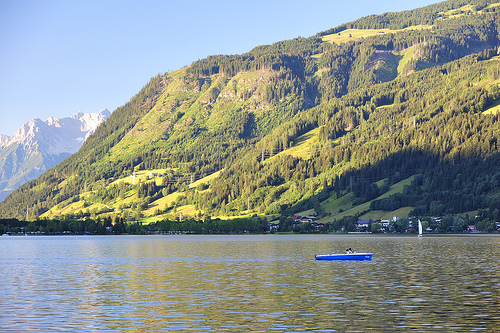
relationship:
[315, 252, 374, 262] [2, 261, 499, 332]
boat on top of water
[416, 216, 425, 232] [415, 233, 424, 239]
sail on top of boat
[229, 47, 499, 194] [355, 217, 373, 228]
green hill behind house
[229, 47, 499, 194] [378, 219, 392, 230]
green hill behind house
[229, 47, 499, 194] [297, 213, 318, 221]
green hill behind house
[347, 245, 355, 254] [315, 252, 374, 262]
person on top of boat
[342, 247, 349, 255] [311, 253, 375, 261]
person on top of boat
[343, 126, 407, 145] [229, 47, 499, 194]
wires on side of hill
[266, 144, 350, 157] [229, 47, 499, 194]
wires on side of hill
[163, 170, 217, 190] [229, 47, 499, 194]
wires on side of hill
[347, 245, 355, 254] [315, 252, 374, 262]
person inside of boat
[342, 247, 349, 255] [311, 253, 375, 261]
person inside of canoe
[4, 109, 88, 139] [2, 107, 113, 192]
snow on top of mountain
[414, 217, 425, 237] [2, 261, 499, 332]
sailboat on top of water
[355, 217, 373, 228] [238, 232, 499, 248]
house on top of water edge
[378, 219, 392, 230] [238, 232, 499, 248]
house on top of water edge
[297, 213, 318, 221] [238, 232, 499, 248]
house on top of water edge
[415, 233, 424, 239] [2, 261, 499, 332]
boat on top of water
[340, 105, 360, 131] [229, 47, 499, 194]
tree on side of mountain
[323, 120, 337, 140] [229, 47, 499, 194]
tree on side of mountain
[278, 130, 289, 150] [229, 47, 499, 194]
tree on side of mountain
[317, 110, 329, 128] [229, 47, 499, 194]
tree on side of mountain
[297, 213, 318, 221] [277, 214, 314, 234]
house surrounded by trees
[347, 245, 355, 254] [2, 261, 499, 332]
person on top of water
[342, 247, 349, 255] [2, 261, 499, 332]
person on top of water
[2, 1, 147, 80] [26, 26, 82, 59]
sky has clouds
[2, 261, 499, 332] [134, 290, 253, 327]
water has ripples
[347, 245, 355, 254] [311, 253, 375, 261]
person inside boat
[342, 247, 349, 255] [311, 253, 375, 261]
person inside boat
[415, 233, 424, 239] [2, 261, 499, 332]
boat in water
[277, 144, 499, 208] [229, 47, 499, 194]
shadow on side of mountain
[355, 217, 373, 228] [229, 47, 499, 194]
house on bottom of hill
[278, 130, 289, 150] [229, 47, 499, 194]
tree growing on mountain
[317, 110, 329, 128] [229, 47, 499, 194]
tree growing on mountain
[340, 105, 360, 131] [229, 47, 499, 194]
tree growing on mountain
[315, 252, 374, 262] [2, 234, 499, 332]
boat on lake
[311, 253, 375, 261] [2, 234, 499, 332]
boat floating on lake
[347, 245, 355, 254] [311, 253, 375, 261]
person sitting in boat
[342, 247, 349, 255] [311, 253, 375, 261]
person sitting in boat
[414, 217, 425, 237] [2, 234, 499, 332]
sail boat on lake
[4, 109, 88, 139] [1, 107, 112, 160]
snow covered mountain top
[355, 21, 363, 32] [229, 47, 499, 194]
green tree on top of mountain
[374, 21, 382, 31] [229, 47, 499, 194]
green tree on top of mountain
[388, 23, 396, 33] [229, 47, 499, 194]
green tree on top of mountain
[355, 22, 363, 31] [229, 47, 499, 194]
green tree on top of mountain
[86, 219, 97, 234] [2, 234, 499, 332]
green tree by lake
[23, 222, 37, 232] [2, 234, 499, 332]
green tree by lake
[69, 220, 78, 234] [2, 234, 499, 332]
green tree by lake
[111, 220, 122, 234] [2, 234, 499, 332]
green tree by lake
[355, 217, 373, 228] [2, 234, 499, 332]
house next to lake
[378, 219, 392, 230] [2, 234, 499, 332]
house next to lake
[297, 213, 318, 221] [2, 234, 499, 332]
house next to lake